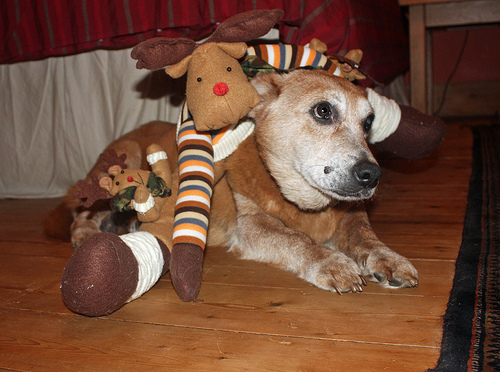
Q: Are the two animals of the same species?
A: No, they are mooses and dogs.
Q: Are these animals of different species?
A: Yes, they are mooses and dogs.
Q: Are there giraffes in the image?
A: No, there are no giraffes.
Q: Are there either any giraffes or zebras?
A: No, there are no giraffes or zebras.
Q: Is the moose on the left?
A: Yes, the moose is on the left of the image.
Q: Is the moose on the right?
A: No, the moose is on the left of the image.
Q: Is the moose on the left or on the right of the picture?
A: The moose is on the left of the image.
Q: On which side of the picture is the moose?
A: The moose is on the left of the image.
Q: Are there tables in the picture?
A: Yes, there is a table.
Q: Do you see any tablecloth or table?
A: Yes, there is a table.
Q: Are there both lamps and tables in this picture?
A: No, there is a table but no lamps.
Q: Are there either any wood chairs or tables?
A: Yes, there is a wood table.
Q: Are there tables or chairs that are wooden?
A: Yes, the table is wooden.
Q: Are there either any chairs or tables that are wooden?
A: Yes, the table is wooden.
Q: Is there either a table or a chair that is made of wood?
A: Yes, the table is made of wood.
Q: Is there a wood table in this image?
A: Yes, there is a wood table.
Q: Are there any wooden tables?
A: Yes, there is a wood table.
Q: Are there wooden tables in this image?
A: Yes, there is a wood table.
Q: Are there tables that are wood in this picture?
A: Yes, there is a wood table.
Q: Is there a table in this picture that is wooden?
A: Yes, there is a table that is wooden.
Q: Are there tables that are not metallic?
A: Yes, there is a wooden table.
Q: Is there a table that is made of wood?
A: Yes, there is a table that is made of wood.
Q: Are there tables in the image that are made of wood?
A: Yes, there is a table that is made of wood.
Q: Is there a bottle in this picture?
A: No, there are no bottles.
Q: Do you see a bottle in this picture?
A: No, there are no bottles.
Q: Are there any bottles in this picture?
A: No, there are no bottles.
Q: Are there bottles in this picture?
A: No, there are no bottles.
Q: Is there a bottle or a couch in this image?
A: No, there are no bottles or couches.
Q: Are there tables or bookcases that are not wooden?
A: No, there is a table but it is wooden.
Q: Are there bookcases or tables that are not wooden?
A: No, there is a table but it is wooden.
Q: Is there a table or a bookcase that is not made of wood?
A: No, there is a table but it is made of wood.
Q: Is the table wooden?
A: Yes, the table is wooden.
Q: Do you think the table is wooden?
A: Yes, the table is wooden.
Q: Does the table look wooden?
A: Yes, the table is wooden.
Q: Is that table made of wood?
A: Yes, the table is made of wood.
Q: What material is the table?
A: The table is made of wood.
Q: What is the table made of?
A: The table is made of wood.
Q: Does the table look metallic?
A: No, the table is wooden.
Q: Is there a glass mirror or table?
A: No, there is a table but it is wooden.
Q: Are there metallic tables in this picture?
A: No, there is a table but it is wooden.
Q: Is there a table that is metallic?
A: No, there is a table but it is wooden.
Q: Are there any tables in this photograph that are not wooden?
A: No, there is a table but it is wooden.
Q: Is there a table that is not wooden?
A: No, there is a table but it is wooden.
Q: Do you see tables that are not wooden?
A: No, there is a table but it is wooden.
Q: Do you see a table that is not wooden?
A: No, there is a table but it is wooden.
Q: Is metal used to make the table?
A: No, the table is made of wood.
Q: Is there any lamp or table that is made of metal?
A: No, there is a table but it is made of wood.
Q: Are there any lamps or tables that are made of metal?
A: No, there is a table but it is made of wood.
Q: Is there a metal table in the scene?
A: No, there is a table but it is made of wood.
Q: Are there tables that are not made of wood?
A: No, there is a table but it is made of wood.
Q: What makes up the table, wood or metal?
A: The table is made of wood.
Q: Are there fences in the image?
A: No, there are no fences.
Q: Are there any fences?
A: No, there are no fences.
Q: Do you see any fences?
A: No, there are no fences.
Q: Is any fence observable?
A: No, there are no fences.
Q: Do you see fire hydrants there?
A: No, there are no fire hydrants.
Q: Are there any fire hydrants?
A: No, there are no fire hydrants.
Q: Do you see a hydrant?
A: No, there are no fire hydrants.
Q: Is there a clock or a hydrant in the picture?
A: No, there are no fire hydrants or clocks.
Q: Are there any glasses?
A: No, there are no glasses.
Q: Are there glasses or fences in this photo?
A: No, there are no glasses or fences.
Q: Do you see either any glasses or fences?
A: No, there are no glasses or fences.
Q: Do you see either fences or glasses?
A: No, there are no glasses or fences.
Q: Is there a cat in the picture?
A: No, there are no cats.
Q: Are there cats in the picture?
A: No, there are no cats.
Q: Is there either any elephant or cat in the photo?
A: No, there are no cats or elephants.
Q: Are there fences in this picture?
A: No, there are no fences.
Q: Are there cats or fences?
A: No, there are no fences or cats.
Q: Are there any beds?
A: Yes, there is a bed.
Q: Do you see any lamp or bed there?
A: Yes, there is a bed.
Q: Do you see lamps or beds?
A: Yes, there is a bed.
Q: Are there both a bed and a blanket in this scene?
A: No, there is a bed but no blankets.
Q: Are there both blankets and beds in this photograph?
A: No, there is a bed but no blankets.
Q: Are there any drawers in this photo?
A: No, there are no drawers.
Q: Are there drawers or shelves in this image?
A: No, there are no drawers or shelves.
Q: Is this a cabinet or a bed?
A: This is a bed.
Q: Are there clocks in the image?
A: No, there are no clocks.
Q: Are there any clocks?
A: No, there are no clocks.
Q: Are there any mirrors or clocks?
A: No, there are no clocks or mirrors.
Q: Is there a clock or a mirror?
A: No, there are no clocks or mirrors.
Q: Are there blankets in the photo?
A: No, there are no blankets.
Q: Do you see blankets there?
A: No, there are no blankets.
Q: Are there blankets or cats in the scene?
A: No, there are no blankets or cats.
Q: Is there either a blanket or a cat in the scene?
A: No, there are no blankets or cats.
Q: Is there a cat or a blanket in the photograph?
A: No, there are no blankets or cats.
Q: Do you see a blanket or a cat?
A: No, there are no blankets or cats.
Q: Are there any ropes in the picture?
A: No, there are no ropes.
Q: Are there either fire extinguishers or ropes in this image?
A: No, there are no ropes or fire extinguishers.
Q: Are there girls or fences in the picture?
A: No, there are no fences or girls.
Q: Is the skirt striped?
A: Yes, the skirt is striped.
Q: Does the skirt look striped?
A: Yes, the skirt is striped.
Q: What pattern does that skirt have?
A: The skirt has striped pattern.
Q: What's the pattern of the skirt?
A: The skirt is striped.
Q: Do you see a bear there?
A: No, there are no bears.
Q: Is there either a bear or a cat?
A: No, there are no bears or cats.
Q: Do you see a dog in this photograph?
A: Yes, there is a dog.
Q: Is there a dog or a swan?
A: Yes, there is a dog.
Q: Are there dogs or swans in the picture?
A: Yes, there is a dog.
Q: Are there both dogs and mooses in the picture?
A: Yes, there are both a dog and mooses.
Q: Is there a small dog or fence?
A: Yes, there is a small dog.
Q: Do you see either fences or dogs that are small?
A: Yes, the dog is small.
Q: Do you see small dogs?
A: Yes, there is a small dog.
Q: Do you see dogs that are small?
A: Yes, there is a dog that is small.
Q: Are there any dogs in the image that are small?
A: Yes, there is a dog that is small.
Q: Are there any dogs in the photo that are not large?
A: Yes, there is a small dog.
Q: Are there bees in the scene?
A: No, there are no bees.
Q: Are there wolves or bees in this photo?
A: No, there are no bees or wolves.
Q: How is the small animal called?
A: The animal is a dog.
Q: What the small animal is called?
A: The animal is a dog.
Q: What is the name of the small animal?
A: The animal is a dog.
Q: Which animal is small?
A: The animal is a dog.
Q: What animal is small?
A: The animal is a dog.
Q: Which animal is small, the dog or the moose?
A: The dog is small.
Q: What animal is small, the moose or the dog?
A: The dog is small.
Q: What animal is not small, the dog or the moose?
A: The moose is not small.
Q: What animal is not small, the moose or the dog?
A: The moose is not small.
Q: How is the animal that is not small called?
A: The animal is a moose.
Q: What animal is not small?
A: The animal is a moose.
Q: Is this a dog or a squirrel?
A: This is a dog.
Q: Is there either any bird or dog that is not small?
A: No, there is a dog but it is small.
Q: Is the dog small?
A: Yes, the dog is small.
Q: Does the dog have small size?
A: Yes, the dog is small.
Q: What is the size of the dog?
A: The dog is small.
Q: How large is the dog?
A: The dog is small.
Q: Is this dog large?
A: No, the dog is small.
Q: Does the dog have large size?
A: No, the dog is small.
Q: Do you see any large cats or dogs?
A: No, there is a dog but it is small.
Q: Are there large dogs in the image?
A: No, there is a dog but it is small.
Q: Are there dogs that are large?
A: No, there is a dog but it is small.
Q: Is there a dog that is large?
A: No, there is a dog but it is small.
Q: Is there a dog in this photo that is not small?
A: No, there is a dog but it is small.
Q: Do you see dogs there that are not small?
A: No, there is a dog but it is small.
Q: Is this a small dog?
A: Yes, this is a small dog.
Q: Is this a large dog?
A: No, this is a small dog.